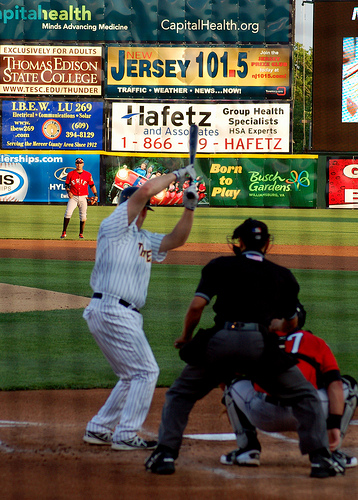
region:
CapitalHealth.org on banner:
[155, 11, 286, 47]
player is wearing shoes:
[64, 403, 161, 463]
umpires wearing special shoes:
[188, 439, 341, 487]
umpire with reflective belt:
[190, 306, 277, 351]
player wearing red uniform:
[61, 155, 99, 231]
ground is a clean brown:
[10, 420, 109, 485]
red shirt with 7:
[269, 328, 319, 356]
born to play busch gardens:
[203, 155, 333, 221]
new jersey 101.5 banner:
[113, 42, 280, 101]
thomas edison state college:
[0, 48, 108, 93]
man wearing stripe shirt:
[80, 173, 144, 452]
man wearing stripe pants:
[72, 168, 150, 443]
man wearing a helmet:
[82, 169, 148, 452]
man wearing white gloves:
[61, 176, 150, 447]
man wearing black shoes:
[71, 176, 159, 449]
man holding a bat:
[59, 114, 195, 445]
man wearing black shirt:
[156, 207, 340, 482]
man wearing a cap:
[49, 152, 93, 247]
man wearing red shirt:
[34, 153, 94, 240]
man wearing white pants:
[45, 156, 91, 246]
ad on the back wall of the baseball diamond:
[112, 100, 299, 157]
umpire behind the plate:
[161, 196, 350, 454]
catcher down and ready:
[243, 312, 339, 470]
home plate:
[179, 425, 237, 447]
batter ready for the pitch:
[86, 193, 170, 454]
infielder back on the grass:
[54, 154, 85, 249]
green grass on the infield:
[10, 317, 62, 371]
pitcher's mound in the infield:
[1, 276, 50, 310]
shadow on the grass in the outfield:
[275, 210, 351, 229]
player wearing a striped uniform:
[84, 206, 169, 419]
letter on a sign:
[108, 47, 127, 83]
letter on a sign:
[125, 55, 140, 81]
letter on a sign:
[137, 56, 153, 80]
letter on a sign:
[151, 56, 166, 77]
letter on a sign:
[163, 57, 178, 81]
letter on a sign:
[175, 56, 191, 77]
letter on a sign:
[221, 135, 236, 151]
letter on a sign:
[234, 136, 246, 150]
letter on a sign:
[245, 133, 254, 151]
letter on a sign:
[254, 135, 267, 152]